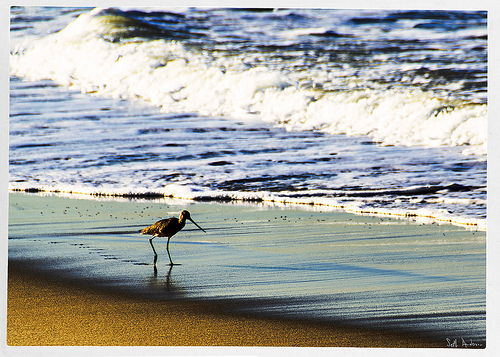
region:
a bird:
[127, 145, 212, 343]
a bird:
[137, 117, 262, 355]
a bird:
[173, 157, 236, 293]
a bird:
[54, 108, 211, 348]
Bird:
[112, 189, 221, 279]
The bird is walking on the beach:
[109, 184, 227, 275]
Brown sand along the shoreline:
[12, 273, 256, 348]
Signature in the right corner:
[431, 323, 490, 354]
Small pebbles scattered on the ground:
[46, 184, 366, 234]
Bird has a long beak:
[170, 201, 215, 239]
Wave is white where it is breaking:
[53, 17, 475, 154]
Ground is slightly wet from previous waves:
[212, 220, 466, 324]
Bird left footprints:
[34, 219, 141, 271]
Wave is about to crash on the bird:
[131, 45, 427, 141]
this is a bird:
[140, 205, 204, 271]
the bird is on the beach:
[138, 195, 208, 283]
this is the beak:
[185, 216, 207, 233]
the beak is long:
[187, 216, 212, 234]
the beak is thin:
[187, 217, 204, 234]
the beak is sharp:
[187, 217, 209, 232]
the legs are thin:
[147, 238, 176, 263]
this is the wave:
[236, 57, 361, 115]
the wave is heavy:
[83, 20, 178, 99]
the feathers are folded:
[147, 217, 176, 232]